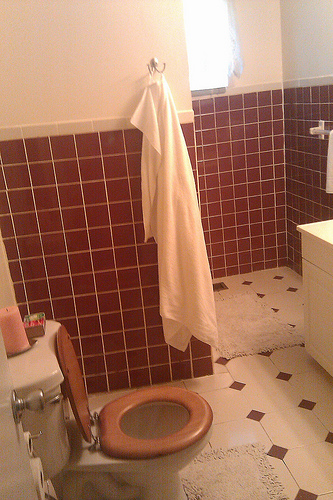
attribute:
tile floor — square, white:
[250, 383, 300, 418]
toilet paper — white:
[30, 456, 51, 499]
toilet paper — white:
[23, 427, 33, 456]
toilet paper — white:
[12, 419, 66, 499]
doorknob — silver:
[12, 387, 45, 423]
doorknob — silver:
[7, 378, 58, 437]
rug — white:
[210, 291, 306, 360]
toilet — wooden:
[50, 337, 235, 465]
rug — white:
[215, 279, 298, 366]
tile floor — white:
[68, 266, 332, 499]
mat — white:
[180, 441, 288, 499]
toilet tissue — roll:
[27, 454, 48, 498]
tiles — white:
[94, 262, 324, 498]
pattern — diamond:
[60, 269, 332, 497]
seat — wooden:
[46, 333, 221, 460]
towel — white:
[271, 112, 329, 202]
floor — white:
[209, 352, 317, 449]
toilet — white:
[8, 310, 217, 498]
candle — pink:
[4, 299, 37, 351]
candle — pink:
[0, 305, 29, 353]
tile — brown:
[23, 144, 118, 263]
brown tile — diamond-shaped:
[244, 406, 267, 423]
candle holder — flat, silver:
[7, 339, 36, 357]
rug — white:
[208, 292, 304, 364]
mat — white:
[242, 297, 291, 344]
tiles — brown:
[217, 340, 312, 468]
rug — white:
[173, 438, 291, 497]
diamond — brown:
[242, 404, 268, 422]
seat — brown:
[51, 318, 214, 463]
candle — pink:
[0, 299, 31, 358]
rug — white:
[182, 442, 292, 498]